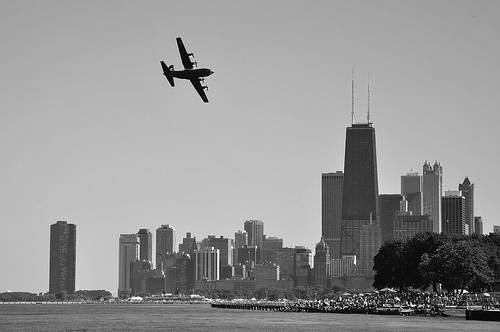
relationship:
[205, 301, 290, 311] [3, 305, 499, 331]
pier in water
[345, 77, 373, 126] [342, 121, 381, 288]
antennas on skyscraper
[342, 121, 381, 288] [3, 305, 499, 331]
skyscraper near water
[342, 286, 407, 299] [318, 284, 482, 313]
umbrellas over people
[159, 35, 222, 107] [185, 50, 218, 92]
plane has propellers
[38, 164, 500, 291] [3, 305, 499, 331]
buildings near water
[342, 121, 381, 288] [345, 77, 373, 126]
skyscraper with two antennas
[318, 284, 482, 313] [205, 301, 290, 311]
people near pier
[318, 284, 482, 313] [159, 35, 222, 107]
people watching plane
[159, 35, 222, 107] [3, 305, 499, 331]
plane flying over water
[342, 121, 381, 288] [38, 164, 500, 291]
skyscraper taller than buildings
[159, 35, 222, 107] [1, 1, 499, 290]
plane in sky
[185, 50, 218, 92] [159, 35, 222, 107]
propellers on plane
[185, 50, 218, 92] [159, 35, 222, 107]
propellers are on plane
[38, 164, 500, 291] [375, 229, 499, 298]
buildings behind trees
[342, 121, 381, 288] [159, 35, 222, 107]
skyscraper behind plane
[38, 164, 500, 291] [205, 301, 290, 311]
buildings past pier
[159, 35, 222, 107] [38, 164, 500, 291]
plane near buildings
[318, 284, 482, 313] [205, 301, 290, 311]
people are on pier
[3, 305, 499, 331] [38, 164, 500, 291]
water in front of buildings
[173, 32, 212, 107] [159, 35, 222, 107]
wings on plane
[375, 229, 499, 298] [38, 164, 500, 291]
trees in front of buildings